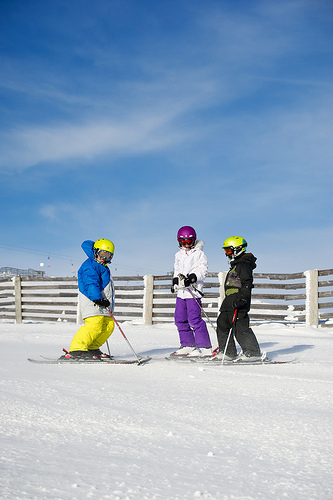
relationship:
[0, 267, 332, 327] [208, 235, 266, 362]
fence behind skier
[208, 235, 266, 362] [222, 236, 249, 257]
skier has helmet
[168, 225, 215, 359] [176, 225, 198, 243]
skier has helmet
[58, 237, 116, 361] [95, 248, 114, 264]
skier wearing snow goggles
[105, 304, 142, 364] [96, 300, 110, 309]
ski pole held in hand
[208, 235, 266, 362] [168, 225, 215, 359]
skier next to skier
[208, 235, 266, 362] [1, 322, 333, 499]
skier standing on snow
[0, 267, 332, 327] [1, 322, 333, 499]
fence along snow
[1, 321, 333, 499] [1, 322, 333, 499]
ground covered in snow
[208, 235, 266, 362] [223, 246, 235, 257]
skier wearing snow goggles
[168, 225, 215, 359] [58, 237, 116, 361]
skier standing with skier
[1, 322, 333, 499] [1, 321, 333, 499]
snow laying on ground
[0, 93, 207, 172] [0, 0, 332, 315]
cloud in middle of sky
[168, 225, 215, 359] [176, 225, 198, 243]
skier wearing helmet